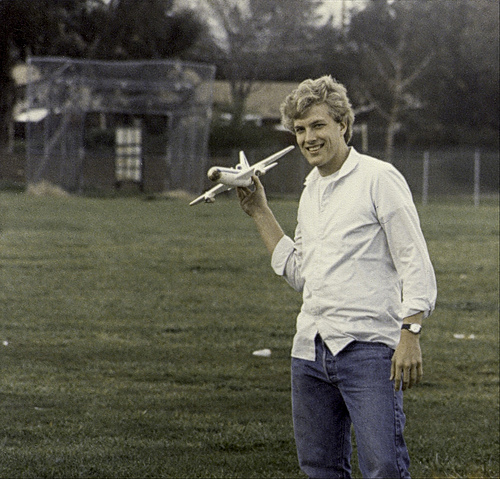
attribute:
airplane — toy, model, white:
[189, 146, 295, 208]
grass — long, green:
[1, 191, 498, 478]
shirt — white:
[268, 147, 437, 361]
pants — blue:
[290, 334, 413, 478]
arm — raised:
[236, 173, 305, 291]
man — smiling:
[237, 74, 438, 478]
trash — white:
[254, 349, 273, 357]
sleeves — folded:
[272, 236, 439, 317]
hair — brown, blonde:
[280, 74, 353, 144]